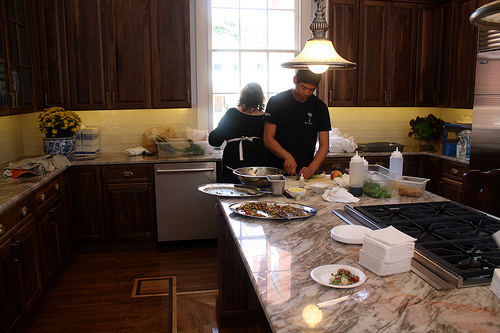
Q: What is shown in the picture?
A: A kitchen.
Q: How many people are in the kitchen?
A: Two.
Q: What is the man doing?
A: Preparing food.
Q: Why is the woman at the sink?
A: Doing dishes.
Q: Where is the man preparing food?
A: The island.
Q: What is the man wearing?
A: A t shirt.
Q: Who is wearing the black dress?
A: The woman.